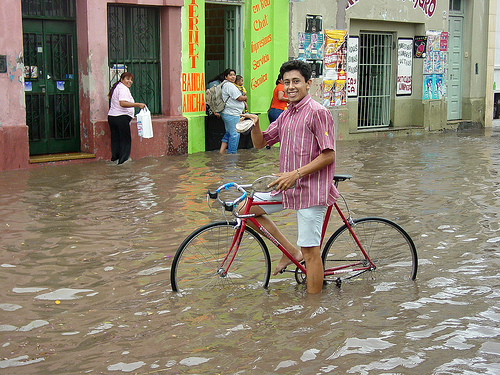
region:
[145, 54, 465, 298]
Man on a bike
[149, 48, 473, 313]
Man on a bike on a flooded street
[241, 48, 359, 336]
Man in red and white striped shirt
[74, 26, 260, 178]
People standing in a flooded street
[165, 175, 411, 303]
Red bicycle in flooded street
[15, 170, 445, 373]
A flooded street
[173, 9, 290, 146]
A green and orange wall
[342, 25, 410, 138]
Gated iron door front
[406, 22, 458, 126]
Posters on a wall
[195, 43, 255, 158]
Person holding a baby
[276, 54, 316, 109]
the head of a man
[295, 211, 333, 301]
the leg of a man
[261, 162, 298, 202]
the hand of a man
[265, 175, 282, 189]
the finger of a man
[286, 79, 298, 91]
the nose of a man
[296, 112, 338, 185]
the arm of a man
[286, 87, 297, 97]
the mouth of a man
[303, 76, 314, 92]
the ear of a man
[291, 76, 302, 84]
the eye of a man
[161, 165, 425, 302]
a red and black bicycle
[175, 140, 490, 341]
the man is wearing white short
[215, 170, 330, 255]
the man is wearing white short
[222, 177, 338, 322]
the man is wearing white short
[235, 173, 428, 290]
the man is wearing white short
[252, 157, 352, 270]
the man is wearing white short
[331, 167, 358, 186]
a black bicycle seat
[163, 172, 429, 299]
a bicycle in the water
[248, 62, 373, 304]
Man sitting on his bike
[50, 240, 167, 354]
Dirty flood water in the street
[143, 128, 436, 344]
The bike is red in color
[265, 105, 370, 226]
Man wearing a short sleeve shirt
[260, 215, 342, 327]
Man not wearing shoes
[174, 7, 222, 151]
Sign outside of building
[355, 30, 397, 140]
Bars in front of door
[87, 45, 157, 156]
Woman holding a bag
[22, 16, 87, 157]
Green door on side of building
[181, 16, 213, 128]
Orange writing on outside of building